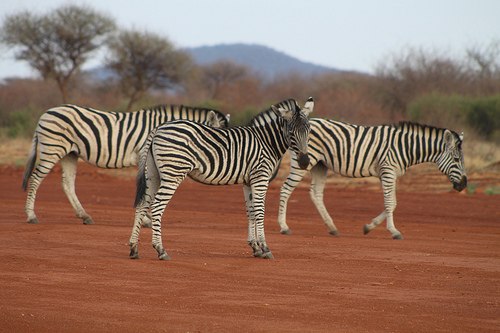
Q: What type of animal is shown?
A: Zebra.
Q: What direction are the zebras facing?
A: Right.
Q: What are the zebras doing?
A: Walking.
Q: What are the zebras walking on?
A: Dirt.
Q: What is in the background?
A: Mountain.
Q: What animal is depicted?
A: Zebra.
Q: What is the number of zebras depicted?
A: 3.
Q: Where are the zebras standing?
A: Natural habitat.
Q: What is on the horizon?
A: Mountain.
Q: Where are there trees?
A: Behind zebras.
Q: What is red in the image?
A: Dirt.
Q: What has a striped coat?
A: Zebras.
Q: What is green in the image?
A: Bushes in front of trees.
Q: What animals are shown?
A: Zebras.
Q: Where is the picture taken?
A: The bush.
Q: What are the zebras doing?
A: Standing and walking.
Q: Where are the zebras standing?
A: On the red clay.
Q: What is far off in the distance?
A: Mountains.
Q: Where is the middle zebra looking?
A: At the camera.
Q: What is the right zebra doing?
A: Walking.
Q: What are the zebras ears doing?
A: Perking up.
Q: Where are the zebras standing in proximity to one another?
A: Next to each other.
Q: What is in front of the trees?
A: Yellow grass and zebras on red clay.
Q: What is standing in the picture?
A: Zebras.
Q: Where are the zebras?
A: In the field.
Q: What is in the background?
A: Trees.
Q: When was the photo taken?
A: During the day.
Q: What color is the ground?
A: Brown.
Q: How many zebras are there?
A: Three.